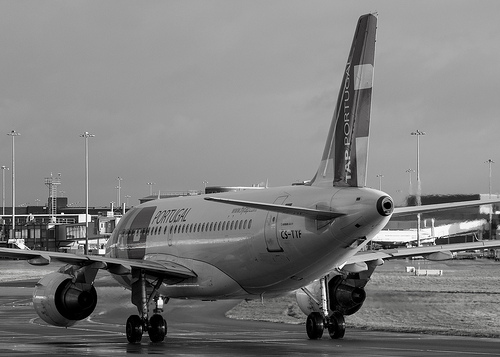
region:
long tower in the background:
[42, 165, 68, 213]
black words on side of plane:
[141, 200, 215, 227]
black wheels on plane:
[113, 298, 182, 343]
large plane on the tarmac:
[51, 13, 436, 299]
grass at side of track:
[396, 290, 453, 318]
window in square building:
[43, 208, 89, 227]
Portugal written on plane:
[151, 203, 193, 222]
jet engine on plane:
[33, 271, 95, 327]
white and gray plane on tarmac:
[5, 15, 499, 340]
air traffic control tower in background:
[44, 174, 58, 215]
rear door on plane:
[264, 195, 284, 253]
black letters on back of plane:
[272, 225, 304, 243]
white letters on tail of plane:
[342, 63, 352, 182]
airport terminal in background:
[1, 207, 121, 254]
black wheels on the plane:
[123, 300, 348, 341]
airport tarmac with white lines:
[1, 260, 498, 355]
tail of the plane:
[317, 6, 386, 188]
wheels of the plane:
[125, 311, 176, 341]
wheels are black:
[306, 305, 349, 340]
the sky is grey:
[181, 58, 239, 90]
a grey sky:
[160, 51, 227, 106]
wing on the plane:
[208, 187, 288, 219]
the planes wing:
[29, 240, 94, 265]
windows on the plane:
[168, 214, 225, 244]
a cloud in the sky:
[143, 108, 202, 144]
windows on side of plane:
[110, 205, 257, 262]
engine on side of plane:
[11, 252, 107, 342]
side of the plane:
[83, 200, 266, 270]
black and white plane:
[13, 62, 440, 323]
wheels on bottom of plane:
[106, 285, 187, 355]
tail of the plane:
[258, 43, 417, 178]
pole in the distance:
[51, 95, 129, 186]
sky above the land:
[110, 55, 239, 143]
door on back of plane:
[252, 184, 295, 264]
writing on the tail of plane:
[321, 48, 371, 188]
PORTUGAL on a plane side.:
[151, 208, 190, 223]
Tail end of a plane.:
[307, 12, 378, 189]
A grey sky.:
[1, 2, 498, 214]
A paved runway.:
[2, 279, 497, 356]